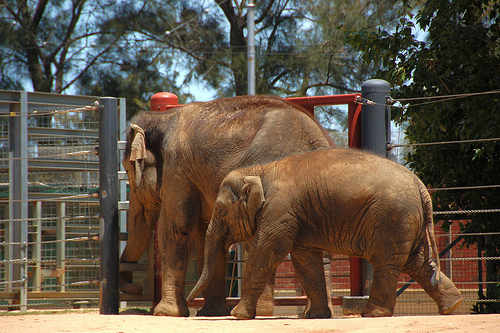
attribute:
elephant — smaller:
[187, 159, 461, 306]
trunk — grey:
[108, 162, 165, 298]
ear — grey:
[243, 175, 265, 238]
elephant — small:
[168, 128, 468, 298]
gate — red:
[145, 92, 363, 308]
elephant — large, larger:
[113, 93, 334, 320]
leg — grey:
[291, 246, 331, 319]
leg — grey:
[224, 282, 268, 322]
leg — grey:
[367, 276, 400, 312]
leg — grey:
[408, 266, 462, 314]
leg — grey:
[157, 272, 188, 320]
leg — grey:
[199, 287, 225, 318]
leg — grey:
[153, 182, 181, 323]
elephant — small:
[181, 147, 467, 318]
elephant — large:
[97, 88, 354, 327]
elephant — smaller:
[270, 159, 441, 287]